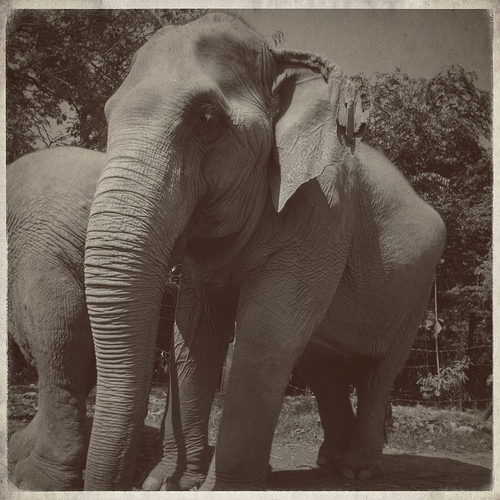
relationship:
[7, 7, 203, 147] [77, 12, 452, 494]
tree behind elephant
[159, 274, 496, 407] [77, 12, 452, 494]
fence behind elephant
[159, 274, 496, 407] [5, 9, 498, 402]
fence in front of trees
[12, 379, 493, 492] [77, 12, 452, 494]
ground beneath elephant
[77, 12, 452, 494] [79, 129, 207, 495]
elephant has trunk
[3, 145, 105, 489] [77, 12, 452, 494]
elephant left of elephant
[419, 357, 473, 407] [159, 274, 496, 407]
leaves stick through fence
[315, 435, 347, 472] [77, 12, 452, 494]
foot of elephant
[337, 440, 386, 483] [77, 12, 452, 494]
foot of elephant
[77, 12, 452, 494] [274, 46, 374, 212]
elephant has ear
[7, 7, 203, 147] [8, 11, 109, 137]
tree in corner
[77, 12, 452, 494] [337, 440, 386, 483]
elephant has foot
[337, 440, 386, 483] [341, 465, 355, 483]
foot has toe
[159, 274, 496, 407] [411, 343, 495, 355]
fence has wire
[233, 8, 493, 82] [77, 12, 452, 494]
sky above elephant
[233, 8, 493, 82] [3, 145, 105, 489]
sky above elephant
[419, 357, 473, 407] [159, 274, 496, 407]
plant near fence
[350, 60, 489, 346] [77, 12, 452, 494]
tree next to elephant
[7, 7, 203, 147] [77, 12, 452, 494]
tree next to elephant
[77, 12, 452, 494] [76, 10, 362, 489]
elephant has head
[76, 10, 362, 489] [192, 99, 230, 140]
head has eye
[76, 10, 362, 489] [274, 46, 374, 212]
head has ear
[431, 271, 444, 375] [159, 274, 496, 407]
pole supports fence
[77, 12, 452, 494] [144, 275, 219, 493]
elephant has leg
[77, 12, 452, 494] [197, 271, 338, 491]
elephant has leg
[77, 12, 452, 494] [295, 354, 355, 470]
elephant has leg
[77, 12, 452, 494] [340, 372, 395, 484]
elephant has leg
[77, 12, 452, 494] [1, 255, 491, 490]
elephant in park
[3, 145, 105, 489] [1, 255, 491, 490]
elephant in park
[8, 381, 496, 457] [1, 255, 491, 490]
vegetation in park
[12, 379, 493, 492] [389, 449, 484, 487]
earth has part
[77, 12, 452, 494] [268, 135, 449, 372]
elephant has body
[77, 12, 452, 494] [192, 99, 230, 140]
elephant has eye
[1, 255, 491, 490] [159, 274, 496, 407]
park has fence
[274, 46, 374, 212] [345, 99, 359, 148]
ear has ring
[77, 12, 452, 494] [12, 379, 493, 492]
elephant on field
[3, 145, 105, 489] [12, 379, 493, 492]
elephant on field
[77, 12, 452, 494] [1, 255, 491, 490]
elephant in pen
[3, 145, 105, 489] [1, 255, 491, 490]
elephant in pen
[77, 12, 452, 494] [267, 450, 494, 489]
elephant casts shadow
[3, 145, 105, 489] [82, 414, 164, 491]
elephant casts shadow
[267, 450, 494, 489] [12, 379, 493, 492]
shadow on ground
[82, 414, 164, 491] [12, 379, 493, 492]
shadow on ground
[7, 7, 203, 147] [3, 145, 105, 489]
tree behind elephant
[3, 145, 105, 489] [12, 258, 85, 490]
elephant has leg